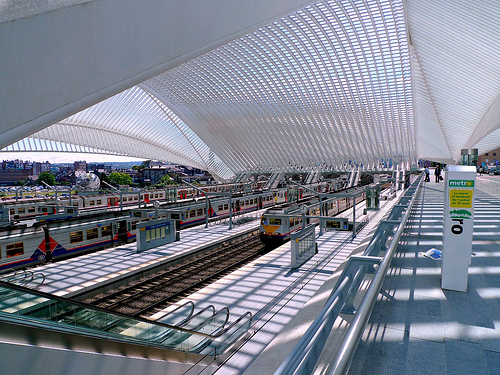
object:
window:
[101, 224, 113, 237]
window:
[8, 237, 23, 257]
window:
[69, 230, 83, 243]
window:
[17, 207, 25, 214]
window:
[27, 206, 35, 213]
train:
[0, 180, 286, 228]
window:
[108, 197, 116, 207]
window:
[190, 209, 196, 218]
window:
[89, 200, 95, 205]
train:
[86, 224, 103, 241]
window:
[86, 227, 99, 240]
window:
[181, 210, 188, 220]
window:
[197, 208, 204, 216]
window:
[155, 193, 159, 198]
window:
[150, 194, 154, 198]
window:
[128, 196, 133, 201]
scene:
[241, 296, 393, 354]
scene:
[303, 359, 425, 371]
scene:
[295, 353, 419, 363]